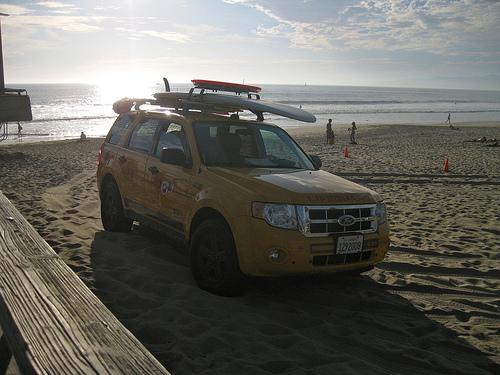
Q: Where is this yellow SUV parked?
A: The beach.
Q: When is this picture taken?
A: Sunrise.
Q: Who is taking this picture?
A: Owner of car.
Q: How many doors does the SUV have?
A: Four.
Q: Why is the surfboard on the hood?
A: For travel.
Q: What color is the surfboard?
A: White.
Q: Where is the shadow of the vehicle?
A: In front.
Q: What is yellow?
A: An SUV.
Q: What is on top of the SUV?
A: A surfboard.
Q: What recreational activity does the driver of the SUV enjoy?
A: Surfing.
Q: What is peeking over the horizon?
A: The sun.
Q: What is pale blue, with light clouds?
A: The sky.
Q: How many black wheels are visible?
A: Two.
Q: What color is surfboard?
A: Gray.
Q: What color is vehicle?
A: Yellow.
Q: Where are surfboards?
A: On vehicle.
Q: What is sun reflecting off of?
A: Water.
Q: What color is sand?
A: Brown.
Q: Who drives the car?
A: Lifeguard.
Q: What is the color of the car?
A: Yellow.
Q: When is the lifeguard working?
A: During the day.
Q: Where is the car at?
A: The beach.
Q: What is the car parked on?
A: Sand.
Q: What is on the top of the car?
A: Surfboard.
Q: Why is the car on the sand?
A: The lifeguard is on duty.